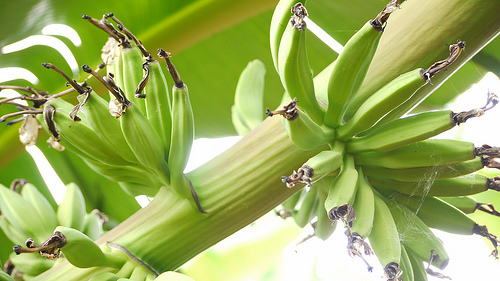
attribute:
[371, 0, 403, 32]
perianth — long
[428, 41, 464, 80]
perianth — long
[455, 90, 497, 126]
perianth — long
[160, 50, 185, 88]
perianth — long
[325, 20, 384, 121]
banana — tiny, thin, exotic, unripe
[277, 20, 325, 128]
banana — tiny, thin, exotic, unripe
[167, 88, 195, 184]
banana — tiny, thin, exotic, unripe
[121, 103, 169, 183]
banana — tiny, thin, exotic, unripe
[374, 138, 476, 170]
banana — tiny, thin, exotic, unripe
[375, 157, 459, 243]
spiderweb — wispy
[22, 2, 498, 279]
limb — yellow green